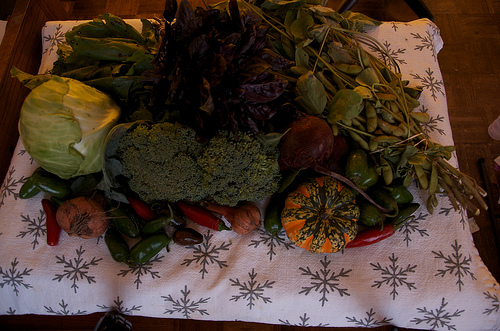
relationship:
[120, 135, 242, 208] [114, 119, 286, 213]
heads of broccoli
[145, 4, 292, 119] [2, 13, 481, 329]
lettuce on table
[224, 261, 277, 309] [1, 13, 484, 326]
snowflake on fabric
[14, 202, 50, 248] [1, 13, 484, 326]
snowflake on fabric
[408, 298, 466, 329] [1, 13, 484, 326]
snowflake on fabric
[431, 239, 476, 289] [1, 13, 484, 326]
snowflake on fabric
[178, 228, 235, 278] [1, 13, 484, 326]
snowflake on fabric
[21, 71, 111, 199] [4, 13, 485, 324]
vegetable on pillow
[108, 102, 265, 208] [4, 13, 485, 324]
vegetable on pillow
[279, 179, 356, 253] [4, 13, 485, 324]
vegetable on pillow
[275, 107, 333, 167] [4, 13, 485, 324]
vegetable on pillow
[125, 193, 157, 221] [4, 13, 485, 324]
peppers on pillow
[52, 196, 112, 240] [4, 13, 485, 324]
vegetables on pillow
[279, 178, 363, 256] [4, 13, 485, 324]
vegetable on pillow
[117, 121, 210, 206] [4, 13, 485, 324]
broccoli on pillow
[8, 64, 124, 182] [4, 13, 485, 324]
vegetable on pillow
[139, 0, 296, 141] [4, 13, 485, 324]
lettuce on pillow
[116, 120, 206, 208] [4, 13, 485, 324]
broccoli on pillow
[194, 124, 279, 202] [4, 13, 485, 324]
broccoli on pillow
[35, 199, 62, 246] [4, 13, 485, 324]
peppers on pillow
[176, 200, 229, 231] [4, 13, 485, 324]
peppers on pillow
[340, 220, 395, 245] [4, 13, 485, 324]
peppers on pillow